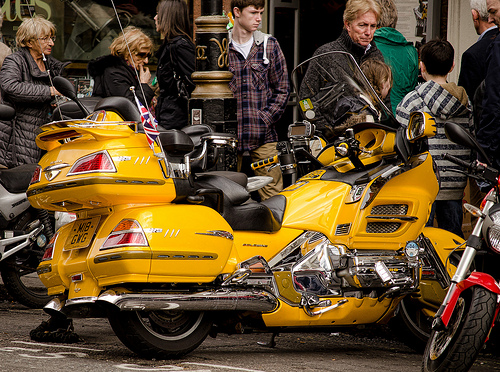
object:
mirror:
[403, 112, 437, 142]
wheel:
[417, 284, 500, 371]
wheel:
[108, 304, 216, 362]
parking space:
[0, 273, 500, 370]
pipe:
[94, 287, 282, 314]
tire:
[107, 305, 218, 360]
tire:
[420, 284, 493, 371]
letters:
[80, 233, 88, 246]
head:
[109, 25, 156, 73]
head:
[230, 1, 265, 32]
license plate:
[61, 214, 104, 252]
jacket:
[149, 34, 198, 129]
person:
[0, 15, 70, 170]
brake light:
[65, 149, 119, 176]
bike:
[26, 50, 475, 358]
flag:
[132, 96, 159, 150]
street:
[0, 270, 500, 371]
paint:
[182, 359, 260, 370]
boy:
[225, 0, 290, 200]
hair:
[418, 39, 455, 78]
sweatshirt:
[224, 25, 289, 152]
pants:
[238, 142, 283, 203]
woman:
[152, 0, 201, 129]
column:
[188, 15, 242, 171]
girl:
[310, 59, 394, 144]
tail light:
[99, 230, 150, 251]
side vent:
[370, 204, 407, 215]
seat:
[195, 170, 288, 234]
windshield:
[290, 50, 390, 130]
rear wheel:
[106, 310, 214, 359]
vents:
[365, 221, 401, 233]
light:
[40, 235, 59, 259]